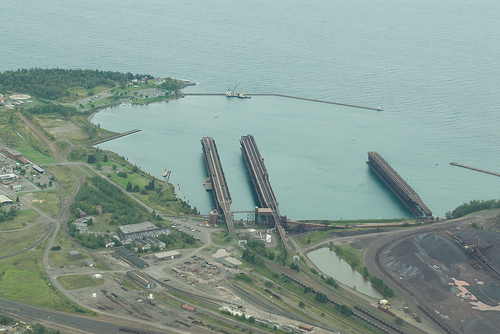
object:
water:
[0, 0, 500, 299]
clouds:
[47, 5, 108, 31]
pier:
[452, 159, 488, 176]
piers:
[197, 122, 234, 222]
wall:
[255, 90, 383, 117]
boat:
[237, 92, 251, 99]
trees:
[33, 75, 62, 97]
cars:
[189, 227, 196, 232]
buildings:
[115, 228, 162, 284]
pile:
[398, 228, 442, 274]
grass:
[297, 230, 341, 246]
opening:
[376, 107, 433, 158]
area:
[191, 63, 359, 154]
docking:
[183, 76, 191, 95]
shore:
[63, 66, 180, 80]